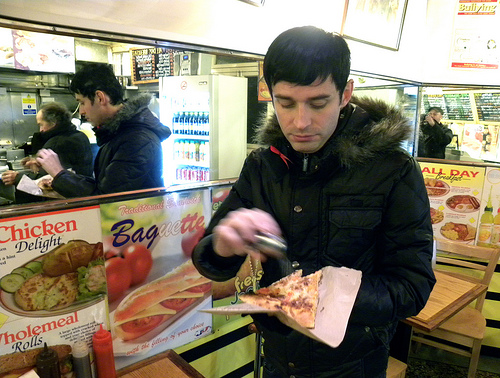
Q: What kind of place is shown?
A: It is a restaurant.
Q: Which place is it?
A: It is a restaurant.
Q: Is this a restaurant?
A: Yes, it is a restaurant.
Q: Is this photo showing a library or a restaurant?
A: It is showing a restaurant.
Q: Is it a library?
A: No, it is a restaurant.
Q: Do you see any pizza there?
A: Yes, there is a pizza.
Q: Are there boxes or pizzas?
A: Yes, there is a pizza.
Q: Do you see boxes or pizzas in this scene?
A: Yes, there is a pizza.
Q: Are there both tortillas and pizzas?
A: No, there is a pizza but no tortillas.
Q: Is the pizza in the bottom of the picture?
A: Yes, the pizza is in the bottom of the image.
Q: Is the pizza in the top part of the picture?
A: No, the pizza is in the bottom of the image.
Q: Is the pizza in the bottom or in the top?
A: The pizza is in the bottom of the image.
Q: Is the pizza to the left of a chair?
A: Yes, the pizza is to the left of a chair.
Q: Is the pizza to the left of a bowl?
A: No, the pizza is to the left of a chair.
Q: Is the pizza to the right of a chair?
A: No, the pizza is to the left of a chair.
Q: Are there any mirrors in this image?
A: Yes, there is a mirror.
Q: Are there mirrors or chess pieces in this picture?
A: Yes, there is a mirror.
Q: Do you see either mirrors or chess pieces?
A: Yes, there is a mirror.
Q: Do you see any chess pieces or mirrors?
A: Yes, there is a mirror.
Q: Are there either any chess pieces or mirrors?
A: Yes, there is a mirror.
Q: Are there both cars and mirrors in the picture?
A: No, there is a mirror but no cars.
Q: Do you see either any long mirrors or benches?
A: Yes, there is a long mirror.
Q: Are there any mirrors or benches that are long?
A: Yes, the mirror is long.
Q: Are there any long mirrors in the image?
A: Yes, there is a long mirror.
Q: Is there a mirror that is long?
A: Yes, there is a mirror that is long.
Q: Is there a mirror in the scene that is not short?
A: Yes, there is a long mirror.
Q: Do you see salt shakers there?
A: No, there are no salt shakers.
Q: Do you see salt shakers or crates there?
A: No, there are no salt shakers or crates.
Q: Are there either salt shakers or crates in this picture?
A: No, there are no salt shakers or crates.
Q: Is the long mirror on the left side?
A: Yes, the mirror is on the left of the image.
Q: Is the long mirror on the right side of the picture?
A: No, the mirror is on the left of the image.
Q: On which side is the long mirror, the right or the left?
A: The mirror is on the left of the image.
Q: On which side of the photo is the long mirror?
A: The mirror is on the left of the image.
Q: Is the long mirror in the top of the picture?
A: Yes, the mirror is in the top of the image.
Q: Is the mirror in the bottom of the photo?
A: No, the mirror is in the top of the image.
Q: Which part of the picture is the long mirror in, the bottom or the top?
A: The mirror is in the top of the image.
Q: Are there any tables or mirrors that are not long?
A: No, there is a mirror but it is long.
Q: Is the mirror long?
A: Yes, the mirror is long.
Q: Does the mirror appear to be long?
A: Yes, the mirror is long.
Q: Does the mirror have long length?
A: Yes, the mirror is long.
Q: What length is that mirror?
A: The mirror is long.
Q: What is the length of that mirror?
A: The mirror is long.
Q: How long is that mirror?
A: The mirror is long.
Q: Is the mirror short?
A: No, the mirror is long.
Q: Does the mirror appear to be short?
A: No, the mirror is long.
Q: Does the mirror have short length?
A: No, the mirror is long.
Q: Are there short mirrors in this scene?
A: No, there is a mirror but it is long.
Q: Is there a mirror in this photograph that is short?
A: No, there is a mirror but it is long.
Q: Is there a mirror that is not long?
A: No, there is a mirror but it is long.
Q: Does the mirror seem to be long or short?
A: The mirror is long.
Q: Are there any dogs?
A: No, there are no dogs.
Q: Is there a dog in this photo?
A: No, there are no dogs.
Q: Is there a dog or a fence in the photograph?
A: No, there are no dogs or fences.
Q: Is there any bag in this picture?
A: No, there are no bags.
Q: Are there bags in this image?
A: No, there are no bags.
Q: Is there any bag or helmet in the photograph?
A: No, there are no bags or helmets.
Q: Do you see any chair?
A: Yes, there is a chair.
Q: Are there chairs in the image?
A: Yes, there is a chair.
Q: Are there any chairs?
A: Yes, there is a chair.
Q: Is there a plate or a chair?
A: Yes, there is a chair.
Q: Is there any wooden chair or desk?
A: Yes, there is a wood chair.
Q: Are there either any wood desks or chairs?
A: Yes, there is a wood chair.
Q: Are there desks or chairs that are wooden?
A: Yes, the chair is wooden.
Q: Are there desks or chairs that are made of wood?
A: Yes, the chair is made of wood.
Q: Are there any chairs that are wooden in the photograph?
A: Yes, there is a wood chair.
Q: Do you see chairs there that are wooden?
A: Yes, there is a chair that is wooden.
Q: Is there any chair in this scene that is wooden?
A: Yes, there is a chair that is wooden.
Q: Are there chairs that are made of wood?
A: Yes, there is a chair that is made of wood.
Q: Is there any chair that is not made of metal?
A: Yes, there is a chair that is made of wood.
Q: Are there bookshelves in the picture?
A: No, there are no bookshelves.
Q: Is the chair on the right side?
A: Yes, the chair is on the right of the image.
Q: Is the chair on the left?
A: No, the chair is on the right of the image.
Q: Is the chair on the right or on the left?
A: The chair is on the right of the image.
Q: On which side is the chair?
A: The chair is on the right of the image.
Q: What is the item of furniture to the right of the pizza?
A: The piece of furniture is a chair.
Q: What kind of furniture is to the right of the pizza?
A: The piece of furniture is a chair.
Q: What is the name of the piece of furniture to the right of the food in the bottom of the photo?
A: The piece of furniture is a chair.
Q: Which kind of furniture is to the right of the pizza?
A: The piece of furniture is a chair.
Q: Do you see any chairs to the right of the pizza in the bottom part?
A: Yes, there is a chair to the right of the pizza.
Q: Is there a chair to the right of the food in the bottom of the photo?
A: Yes, there is a chair to the right of the pizza.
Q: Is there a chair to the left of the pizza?
A: No, the chair is to the right of the pizza.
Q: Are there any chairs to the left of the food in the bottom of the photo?
A: No, the chair is to the right of the pizza.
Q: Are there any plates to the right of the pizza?
A: No, there is a chair to the right of the pizza.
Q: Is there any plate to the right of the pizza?
A: No, there is a chair to the right of the pizza.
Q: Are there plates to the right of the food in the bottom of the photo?
A: No, there is a chair to the right of the pizza.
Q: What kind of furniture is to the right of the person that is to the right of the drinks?
A: The piece of furniture is a chair.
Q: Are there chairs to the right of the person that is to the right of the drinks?
A: Yes, there is a chair to the right of the person.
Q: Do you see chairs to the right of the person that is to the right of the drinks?
A: Yes, there is a chair to the right of the person.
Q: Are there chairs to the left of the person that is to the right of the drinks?
A: No, the chair is to the right of the person.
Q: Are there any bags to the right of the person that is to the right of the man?
A: No, there is a chair to the right of the person.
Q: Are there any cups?
A: No, there are no cups.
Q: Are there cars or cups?
A: No, there are no cups or cars.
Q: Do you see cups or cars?
A: No, there are no cups or cars.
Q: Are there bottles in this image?
A: Yes, there is a bottle.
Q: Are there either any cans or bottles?
A: Yes, there is a bottle.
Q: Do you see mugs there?
A: No, there are no mugs.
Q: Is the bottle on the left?
A: Yes, the bottle is on the left of the image.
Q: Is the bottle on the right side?
A: No, the bottle is on the left of the image.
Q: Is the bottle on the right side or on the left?
A: The bottle is on the left of the image.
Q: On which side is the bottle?
A: The bottle is on the left of the image.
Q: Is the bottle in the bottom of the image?
A: Yes, the bottle is in the bottom of the image.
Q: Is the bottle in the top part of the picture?
A: No, the bottle is in the bottom of the image.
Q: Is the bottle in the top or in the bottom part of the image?
A: The bottle is in the bottom of the image.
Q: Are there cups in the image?
A: No, there are no cups.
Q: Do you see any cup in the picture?
A: No, there are no cups.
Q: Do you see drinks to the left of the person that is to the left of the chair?
A: Yes, there are drinks to the left of the person.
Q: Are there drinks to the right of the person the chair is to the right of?
A: No, the drinks are to the left of the person.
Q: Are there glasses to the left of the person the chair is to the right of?
A: No, there are drinks to the left of the person.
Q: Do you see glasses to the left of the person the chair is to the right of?
A: No, there are drinks to the left of the person.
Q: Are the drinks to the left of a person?
A: Yes, the drinks are to the left of a person.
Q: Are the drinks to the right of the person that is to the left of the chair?
A: No, the drinks are to the left of the person.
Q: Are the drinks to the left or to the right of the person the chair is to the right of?
A: The drinks are to the left of the person.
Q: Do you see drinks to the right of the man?
A: Yes, there are drinks to the right of the man.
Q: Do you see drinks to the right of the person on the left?
A: Yes, there are drinks to the right of the man.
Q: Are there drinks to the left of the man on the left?
A: No, the drinks are to the right of the man.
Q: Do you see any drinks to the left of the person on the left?
A: No, the drinks are to the right of the man.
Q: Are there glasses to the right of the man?
A: No, there are drinks to the right of the man.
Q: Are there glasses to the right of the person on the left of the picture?
A: No, there are drinks to the right of the man.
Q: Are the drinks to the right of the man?
A: Yes, the drinks are to the right of the man.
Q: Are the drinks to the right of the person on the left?
A: Yes, the drinks are to the right of the man.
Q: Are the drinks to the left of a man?
A: No, the drinks are to the right of a man.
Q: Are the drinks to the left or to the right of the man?
A: The drinks are to the right of the man.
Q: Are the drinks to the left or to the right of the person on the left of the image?
A: The drinks are to the right of the man.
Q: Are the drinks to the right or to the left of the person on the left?
A: The drinks are to the right of the man.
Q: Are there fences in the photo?
A: No, there are no fences.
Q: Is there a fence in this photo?
A: No, there are no fences.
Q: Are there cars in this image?
A: No, there are no cars.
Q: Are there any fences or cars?
A: No, there are no cars or fences.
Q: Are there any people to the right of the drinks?
A: Yes, there is a person to the right of the drinks.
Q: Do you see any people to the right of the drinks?
A: Yes, there is a person to the right of the drinks.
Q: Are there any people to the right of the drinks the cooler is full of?
A: Yes, there is a person to the right of the drinks.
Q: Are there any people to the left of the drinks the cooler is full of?
A: No, the person is to the right of the drinks.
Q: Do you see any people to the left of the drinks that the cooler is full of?
A: No, the person is to the right of the drinks.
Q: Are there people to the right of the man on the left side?
A: Yes, there is a person to the right of the man.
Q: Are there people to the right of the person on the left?
A: Yes, there is a person to the right of the man.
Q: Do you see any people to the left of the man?
A: No, the person is to the right of the man.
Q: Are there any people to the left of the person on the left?
A: No, the person is to the right of the man.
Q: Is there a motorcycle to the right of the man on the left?
A: No, there is a person to the right of the man.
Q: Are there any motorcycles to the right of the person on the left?
A: No, there is a person to the right of the man.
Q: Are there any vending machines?
A: No, there are no vending machines.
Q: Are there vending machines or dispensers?
A: No, there are no vending machines or dispensers.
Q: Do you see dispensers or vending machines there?
A: No, there are no vending machines or dispensers.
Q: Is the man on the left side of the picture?
A: Yes, the man is on the left of the image.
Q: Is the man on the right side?
A: No, the man is on the left of the image.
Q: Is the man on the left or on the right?
A: The man is on the left of the image.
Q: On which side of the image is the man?
A: The man is on the left of the image.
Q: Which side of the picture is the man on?
A: The man is on the left of the image.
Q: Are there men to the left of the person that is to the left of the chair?
A: Yes, there is a man to the left of the person.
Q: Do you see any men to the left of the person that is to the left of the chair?
A: Yes, there is a man to the left of the person.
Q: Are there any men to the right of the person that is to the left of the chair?
A: No, the man is to the left of the person.